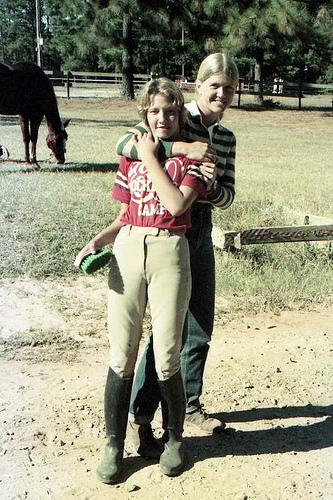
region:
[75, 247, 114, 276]
Brush in girl's hand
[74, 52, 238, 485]
Woman with arm around girl's neck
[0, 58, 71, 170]
Horse in the field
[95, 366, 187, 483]
Tall rubber boots on girl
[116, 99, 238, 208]
Striped shirt on woman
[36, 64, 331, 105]
Wooden fence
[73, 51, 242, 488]
two girls are standing together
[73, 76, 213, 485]
young girl holding a horse brush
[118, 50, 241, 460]
girl with arm around the other girl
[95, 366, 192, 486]
girl's black, warn boots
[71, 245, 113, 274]
green horse brush held by girl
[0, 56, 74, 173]
brown horse grazing in field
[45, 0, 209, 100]
tall green pine tree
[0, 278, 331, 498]
brown dirt road girls are standing on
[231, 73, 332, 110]
wooden fence enclosing horse pasture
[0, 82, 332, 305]
green grass providing food for horse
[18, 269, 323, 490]
The ground has a dirt patch.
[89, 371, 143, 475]
The left boot the woman is wearing.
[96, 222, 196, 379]
The woman is wearing a beige pant.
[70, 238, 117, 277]
The woman is holding a scrub brush.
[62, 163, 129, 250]
The left hand of the woman is holding something.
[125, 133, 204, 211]
The right hand of the woman.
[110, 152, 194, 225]
The woman is wearing a red shirt.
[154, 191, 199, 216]
The elbow of the woman.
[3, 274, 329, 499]
The dirt patch on the ground.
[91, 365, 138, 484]
The left boot the woman is wearing.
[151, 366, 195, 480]
The right boot the woman is wearing.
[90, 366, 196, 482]
The woman is wearing a pair of boots.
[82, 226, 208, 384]
The woman is wearing a beige pant.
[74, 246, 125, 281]
The woman has a scrub brush in her left hand.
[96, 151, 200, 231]
The woman is wearing a red shirt.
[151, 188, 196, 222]
The elbow of the woman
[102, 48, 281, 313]
two girls are hugging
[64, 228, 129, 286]
girl holding a brush used for horses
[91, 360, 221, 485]
boots worn when working in a stall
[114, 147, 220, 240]
red shirt with white writing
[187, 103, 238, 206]
green long sleeved shirt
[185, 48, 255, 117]
lady with long hair pulled into ponytail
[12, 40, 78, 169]
horse in the field grazing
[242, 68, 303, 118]
wooden split rail fence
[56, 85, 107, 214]
field the horse is grazing in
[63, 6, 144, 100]
a pine tree by the fence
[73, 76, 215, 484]
girl wearing knee length black riding boots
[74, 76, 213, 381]
girl wearing slim khaki riding pants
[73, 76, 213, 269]
girl wearing red short sleeved t-shirt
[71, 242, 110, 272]
green object in girl's right hand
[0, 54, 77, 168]
brown horse eating grass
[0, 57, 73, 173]
horse eating grass in field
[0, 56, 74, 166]
Horse grazing on grass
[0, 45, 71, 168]
Horse in field grazing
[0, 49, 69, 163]
Horse standing on green grass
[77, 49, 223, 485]
two girls standing on dirt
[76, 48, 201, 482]
girls standing in the dirt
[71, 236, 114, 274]
Green brush in girl's hand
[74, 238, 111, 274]
Green brush being held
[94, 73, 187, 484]
Girl wearing tan pants